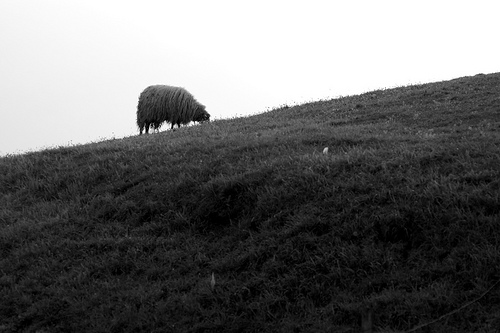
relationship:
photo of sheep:
[6, 3, 497, 328] [133, 81, 219, 135]